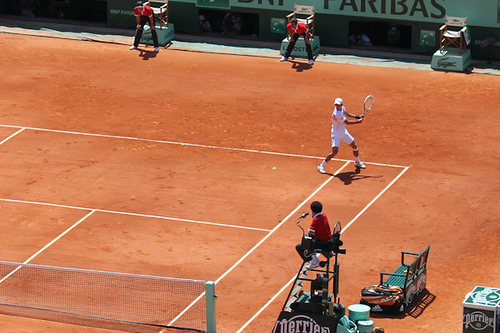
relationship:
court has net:
[3, 34, 490, 270] [2, 261, 216, 332]